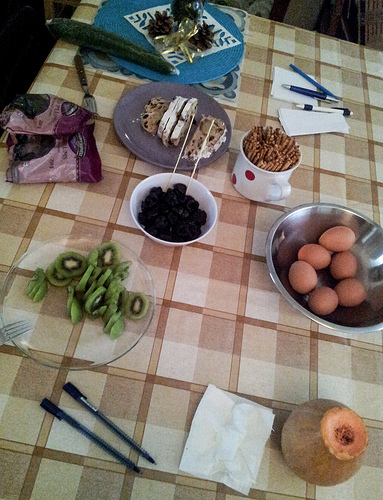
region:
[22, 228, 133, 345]
kiwi slices on plate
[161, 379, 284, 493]
white napkin on a table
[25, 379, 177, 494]
blue pens on table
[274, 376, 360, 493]
fruit on a table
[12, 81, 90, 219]
two pink and dark pink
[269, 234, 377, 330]
brown eggs and silver bowl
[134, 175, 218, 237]
black olives in bowl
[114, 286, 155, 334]
green kiwi with white center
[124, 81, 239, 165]
white bread with purple plate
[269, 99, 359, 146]
blue and white pen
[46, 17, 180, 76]
A long skinny green squash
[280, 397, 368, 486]
A squash with the top cut off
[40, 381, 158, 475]
A pair of blue ink pens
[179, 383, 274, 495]
A folded white napkin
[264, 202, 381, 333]
A stainless steel bowl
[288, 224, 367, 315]
Half a dozen brown eggs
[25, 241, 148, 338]
A pile of sliced kiwi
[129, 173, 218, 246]
A bowl full of black fruit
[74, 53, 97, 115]
A fork with a wooden handle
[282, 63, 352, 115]
A grouping of three pens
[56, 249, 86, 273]
Small green kiwi on clear glass round plate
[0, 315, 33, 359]
Fork on clear glass round plate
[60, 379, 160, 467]
Blue pen near white napkin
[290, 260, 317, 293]
Small brown egg in steel bowl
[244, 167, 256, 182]
Red circular dot on white mug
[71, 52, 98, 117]
Fork near plastic bag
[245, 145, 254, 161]
Pretzel stick in white mug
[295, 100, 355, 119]
White pen next to white paper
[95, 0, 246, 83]
Blue place mat next to round purple plate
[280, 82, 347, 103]
Blue pen on top of white paper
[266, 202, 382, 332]
Basin on the table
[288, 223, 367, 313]
Eggs in the basin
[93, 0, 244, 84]
Blue plate on the table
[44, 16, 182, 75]
Cucumber on the blue plate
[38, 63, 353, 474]
Pens on the table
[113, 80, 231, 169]
Purple plate on the table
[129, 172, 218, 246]
White bowl on the plate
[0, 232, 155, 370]
Glass plate on the table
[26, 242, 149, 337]
Sliced kiwis on the plate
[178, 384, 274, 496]
Napkin on the table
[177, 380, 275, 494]
White napkin next to blue pen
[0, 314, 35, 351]
Fork on clear round plate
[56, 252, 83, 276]
Green kiwi on clear round plate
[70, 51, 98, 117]
Fork next to plastic bag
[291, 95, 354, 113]
White pen next to blue pen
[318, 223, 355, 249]
Round brown egg in steel mixing bowl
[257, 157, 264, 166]
Pretzel stick in white mug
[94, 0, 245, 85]
Blue place mat near blue pen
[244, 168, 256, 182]
Red dot on white mug